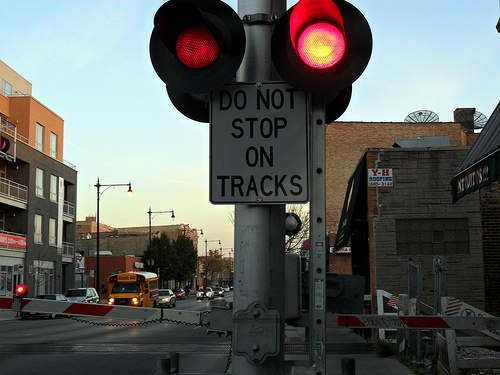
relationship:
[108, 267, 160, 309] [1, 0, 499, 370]
bus approaching rail crossing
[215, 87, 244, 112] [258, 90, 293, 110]
do in front of not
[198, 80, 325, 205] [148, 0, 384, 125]
sign under lights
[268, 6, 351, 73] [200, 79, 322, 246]
light above sign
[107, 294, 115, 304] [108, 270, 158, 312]
light mounted on bus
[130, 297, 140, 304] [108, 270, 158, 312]
light mounted on bus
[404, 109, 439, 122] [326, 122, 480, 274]
satellite sitting on top of building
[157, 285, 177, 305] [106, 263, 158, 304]
car behind bus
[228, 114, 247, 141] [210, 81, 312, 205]
letter on sign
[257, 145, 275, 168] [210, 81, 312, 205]
black letter on sign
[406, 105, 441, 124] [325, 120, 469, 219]
satellite on top of building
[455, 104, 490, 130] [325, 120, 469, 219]
satellite on top of building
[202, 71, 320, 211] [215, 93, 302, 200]
sign board has letters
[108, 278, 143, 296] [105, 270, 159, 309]
windshield on bus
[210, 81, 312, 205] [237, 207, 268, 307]
sign on gray pole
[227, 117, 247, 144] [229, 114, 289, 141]
s in stop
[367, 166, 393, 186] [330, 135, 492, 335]
sign on a building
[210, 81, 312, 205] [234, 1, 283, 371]
sign on a pole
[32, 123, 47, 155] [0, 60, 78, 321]
window on building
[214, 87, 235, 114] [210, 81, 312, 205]
letter on sign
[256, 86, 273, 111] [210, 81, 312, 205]
black letter on sign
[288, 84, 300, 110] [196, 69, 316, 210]
letter on sign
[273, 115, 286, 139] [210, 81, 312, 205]
letter on sign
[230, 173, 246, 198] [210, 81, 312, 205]
black letter on sign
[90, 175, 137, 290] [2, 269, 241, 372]
street lamp along roadside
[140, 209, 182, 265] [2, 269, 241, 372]
street lamp along roadside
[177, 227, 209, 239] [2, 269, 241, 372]
street lamp along roadside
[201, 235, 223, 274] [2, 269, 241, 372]
street lamp along roadside